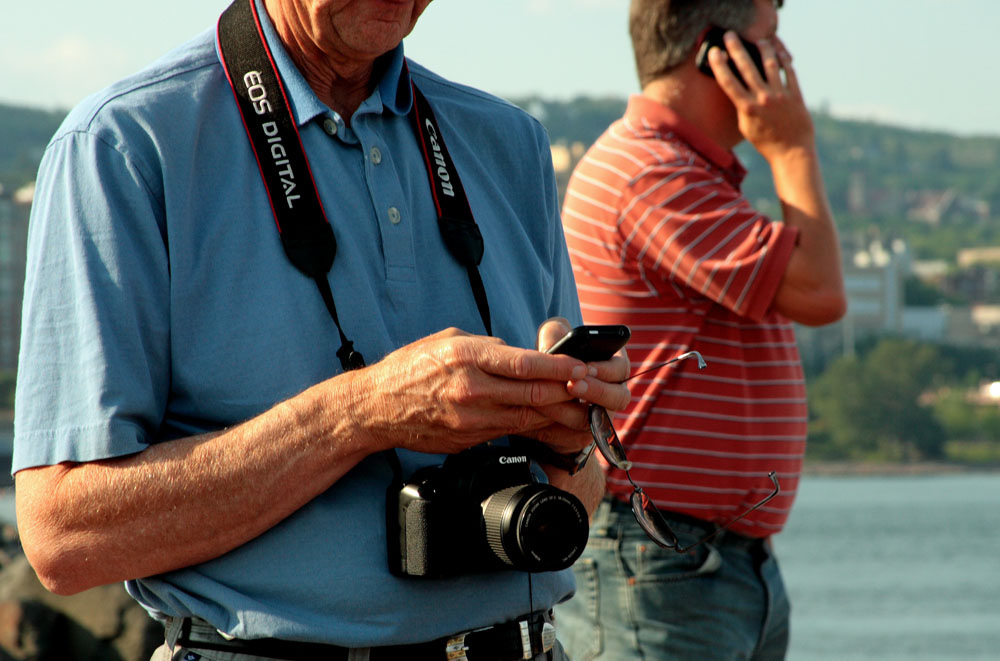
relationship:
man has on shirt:
[551, 0, 845, 660] [597, 136, 742, 303]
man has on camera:
[10, 0, 632, 661] [395, 458, 584, 568]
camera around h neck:
[395, 458, 584, 568] [262, 12, 369, 124]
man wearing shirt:
[18, 34, 587, 644] [18, 45, 578, 621]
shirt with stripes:
[553, 101, 834, 531] [617, 161, 706, 251]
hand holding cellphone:
[376, 318, 631, 454] [498, 285, 619, 432]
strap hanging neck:
[211, 3, 574, 597] [2, 9, 591, 605]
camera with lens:
[389, 452, 590, 577] [464, 458, 576, 563]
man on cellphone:
[551, 0, 845, 660] [691, 45, 794, 117]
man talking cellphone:
[551, 0, 845, 660] [691, 45, 794, 117]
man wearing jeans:
[515, 5, 871, 645] [577, 507, 795, 650]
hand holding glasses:
[415, 321, 593, 475] [511, 289, 629, 399]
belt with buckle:
[353, 600, 540, 658] [458, 600, 561, 649]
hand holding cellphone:
[376, 318, 631, 454] [502, 289, 612, 409]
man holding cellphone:
[10, 0, 632, 661] [521, 263, 608, 428]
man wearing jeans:
[551, 0, 845, 660] [590, 476, 762, 650]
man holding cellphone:
[10, 0, 632, 661] [541, 296, 631, 388]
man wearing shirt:
[10, 0, 632, 661] [145, 118, 421, 399]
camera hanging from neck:
[389, 452, 590, 577] [221, 9, 417, 149]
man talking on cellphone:
[551, 0, 845, 660] [672, 10, 775, 102]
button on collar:
[336, 118, 396, 174] [267, 59, 437, 162]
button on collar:
[330, 116, 382, 205] [281, 76, 399, 154]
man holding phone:
[10, 0, 632, 661] [503, 287, 624, 441]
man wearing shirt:
[551, 0, 845, 660] [627, 269, 721, 518]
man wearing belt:
[10, 0, 632, 661] [167, 610, 414, 657]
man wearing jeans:
[551, 0, 845, 660] [600, 492, 803, 630]